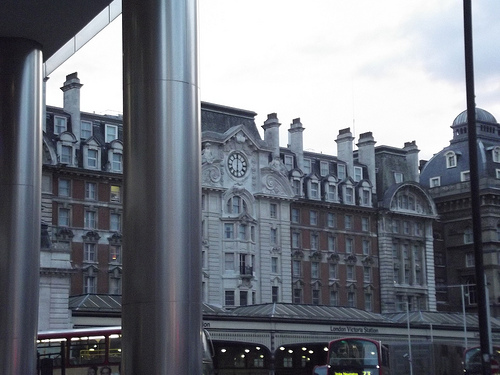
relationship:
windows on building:
[287, 195, 391, 302] [54, 60, 460, 310]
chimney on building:
[264, 98, 355, 174] [54, 60, 460, 310]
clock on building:
[228, 138, 257, 166] [54, 60, 460, 310]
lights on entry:
[392, 325, 448, 362] [361, 312, 432, 375]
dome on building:
[444, 103, 496, 151] [54, 60, 460, 310]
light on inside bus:
[37, 325, 124, 343] [39, 327, 129, 371]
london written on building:
[324, 320, 384, 330] [31, 66, 498, 373]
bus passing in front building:
[320, 327, 387, 372] [41, 70, 498, 342]